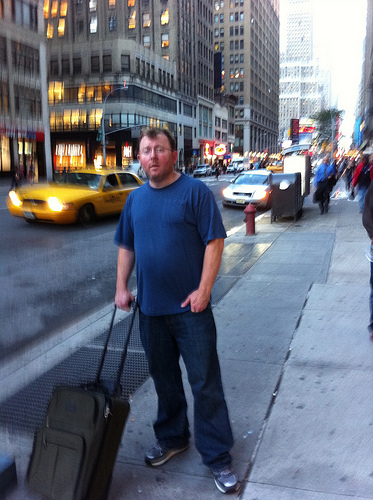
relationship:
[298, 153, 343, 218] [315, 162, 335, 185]
man wearing shirt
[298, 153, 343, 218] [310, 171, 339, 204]
man carrying jacket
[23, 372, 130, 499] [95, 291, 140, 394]
suitcase has handle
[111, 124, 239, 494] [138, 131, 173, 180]
man has face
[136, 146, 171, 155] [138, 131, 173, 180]
glasses on face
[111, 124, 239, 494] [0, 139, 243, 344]
man standing on street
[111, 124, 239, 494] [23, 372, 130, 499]
man has suitcase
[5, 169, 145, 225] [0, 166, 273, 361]
taxi in street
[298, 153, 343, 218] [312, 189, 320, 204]
man holding briefcase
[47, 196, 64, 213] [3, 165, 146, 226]
light on taxi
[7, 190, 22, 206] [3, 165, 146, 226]
light on taxi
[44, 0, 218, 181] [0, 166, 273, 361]
building on other side of street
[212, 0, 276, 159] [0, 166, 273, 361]
building on other side of street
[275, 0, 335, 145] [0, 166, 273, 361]
building on other side of street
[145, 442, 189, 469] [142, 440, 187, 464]
sneaker on foot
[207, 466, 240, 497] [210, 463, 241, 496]
sneaker on foot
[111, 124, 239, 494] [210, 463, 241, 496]
man has foot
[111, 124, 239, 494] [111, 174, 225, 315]
man wearing shirt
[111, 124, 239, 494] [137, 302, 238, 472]
man wearing jeans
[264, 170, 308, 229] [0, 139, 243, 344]
mail box on street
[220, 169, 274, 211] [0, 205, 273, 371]
car beside curb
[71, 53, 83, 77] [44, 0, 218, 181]
window on building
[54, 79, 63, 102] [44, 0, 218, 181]
window on building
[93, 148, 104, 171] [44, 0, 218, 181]
window on building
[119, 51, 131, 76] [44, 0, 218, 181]
window on building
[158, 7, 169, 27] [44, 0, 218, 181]
window on building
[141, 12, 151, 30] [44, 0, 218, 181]
window on building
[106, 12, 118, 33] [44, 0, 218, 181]
window on building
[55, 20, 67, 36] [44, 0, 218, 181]
window on building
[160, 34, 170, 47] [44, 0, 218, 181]
window on building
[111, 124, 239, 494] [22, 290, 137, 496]
man with suitcase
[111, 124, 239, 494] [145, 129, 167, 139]
man with peak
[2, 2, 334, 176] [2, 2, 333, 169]
skyscrapers have row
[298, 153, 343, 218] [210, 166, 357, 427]
man on sidewalk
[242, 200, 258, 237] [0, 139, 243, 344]
hydrant by street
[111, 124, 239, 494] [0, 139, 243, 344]
man standing by street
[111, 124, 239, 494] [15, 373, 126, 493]
man with suitcase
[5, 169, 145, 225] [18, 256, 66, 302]
taxi on road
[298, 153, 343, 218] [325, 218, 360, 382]
man walking sidewalk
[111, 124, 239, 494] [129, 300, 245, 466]
man in jeans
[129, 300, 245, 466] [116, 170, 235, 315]
jeans in t-shirt.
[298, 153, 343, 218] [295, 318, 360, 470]
man on sidewalk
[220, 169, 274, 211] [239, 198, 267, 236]
car parked curb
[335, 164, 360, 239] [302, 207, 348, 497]
man walking sidewalk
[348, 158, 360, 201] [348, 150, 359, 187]
person wearing jacket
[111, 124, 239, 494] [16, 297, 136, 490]
man holding suitcase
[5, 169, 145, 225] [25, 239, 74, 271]
taxi driving road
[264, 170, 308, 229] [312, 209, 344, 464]
mail box on sidewalk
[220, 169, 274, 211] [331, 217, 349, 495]
car parked sidewalk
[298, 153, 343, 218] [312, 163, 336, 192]
man wearing shirt